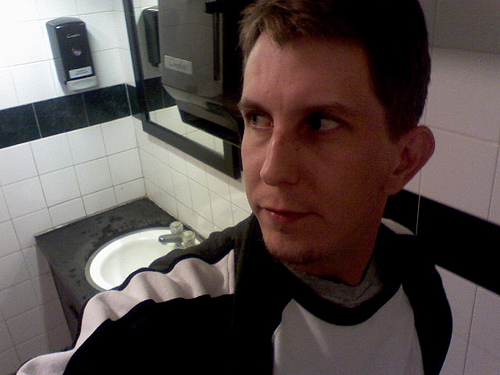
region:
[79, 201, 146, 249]
splashes of water on the counter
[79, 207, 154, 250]
splashes of water on the counter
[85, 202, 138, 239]
splashes of water on the counter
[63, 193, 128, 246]
splashes of water on the counter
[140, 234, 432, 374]
man's top is black and white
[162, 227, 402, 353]
man's top is black and white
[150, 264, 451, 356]
man's top is black and white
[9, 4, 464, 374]
MAN IN BLACK AND WHITE SHIRT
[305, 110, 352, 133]
EYE OF MAN IN BLACK AND WHITE SHIRT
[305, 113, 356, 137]
EYE OF MAN IN SHIRT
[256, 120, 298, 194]
NOSE OF MAN IN SHIRT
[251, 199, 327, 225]
MOUTH OF MAN IN SHIRT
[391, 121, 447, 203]
EAR OF MAN IN SH IRT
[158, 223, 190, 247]
FAUCET OF BATHROOM SINK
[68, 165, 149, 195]
PART OF WHITE TILE WALL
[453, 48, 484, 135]
PART OF WHITE TILE WALL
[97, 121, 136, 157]
white tile on wall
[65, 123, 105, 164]
white tile on wall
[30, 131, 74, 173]
white tile on wall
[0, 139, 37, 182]
white tile on wall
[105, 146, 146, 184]
white tile on wall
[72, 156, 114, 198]
white tile on wall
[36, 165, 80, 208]
white tile on wall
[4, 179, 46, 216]
white tile on wall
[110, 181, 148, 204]
white tile on wall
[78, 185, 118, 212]
white tile on wall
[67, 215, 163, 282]
water is on the sink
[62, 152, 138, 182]
the white tile on the wall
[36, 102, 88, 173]
the wall is tiled black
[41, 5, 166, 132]
a soap dispenser is on the wall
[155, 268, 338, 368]
the man has a striped shirt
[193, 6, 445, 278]
head of a person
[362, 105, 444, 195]
an ear of a person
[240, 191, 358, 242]
mouth of a person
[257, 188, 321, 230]
lip of a person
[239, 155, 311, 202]
a nose of a person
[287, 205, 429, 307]
neck of a person